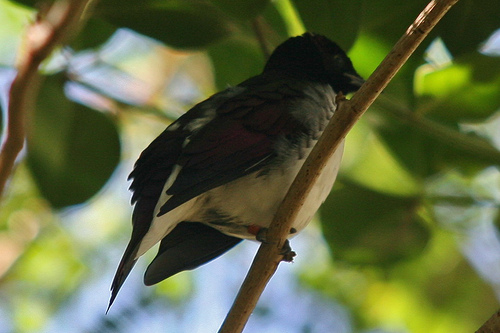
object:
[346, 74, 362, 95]
beak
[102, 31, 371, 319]
bird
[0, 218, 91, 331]
yellow leaf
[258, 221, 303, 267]
legs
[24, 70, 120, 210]
leaf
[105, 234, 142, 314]
tail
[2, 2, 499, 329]
photo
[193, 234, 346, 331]
sky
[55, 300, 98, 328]
sky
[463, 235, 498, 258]
sky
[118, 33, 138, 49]
sky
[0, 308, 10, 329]
sky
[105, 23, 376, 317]
bird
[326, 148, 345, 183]
white chest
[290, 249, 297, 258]
toes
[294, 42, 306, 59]
feathers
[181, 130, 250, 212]
feathers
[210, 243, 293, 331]
twig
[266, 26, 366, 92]
head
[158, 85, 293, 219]
wing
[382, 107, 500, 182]
leaves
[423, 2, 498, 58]
leaves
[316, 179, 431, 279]
leaves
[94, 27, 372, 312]
bird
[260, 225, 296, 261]
feet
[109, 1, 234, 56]
leaves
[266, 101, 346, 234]
breast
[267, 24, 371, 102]
head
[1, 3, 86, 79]
branch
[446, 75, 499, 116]
leaf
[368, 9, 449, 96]
branch